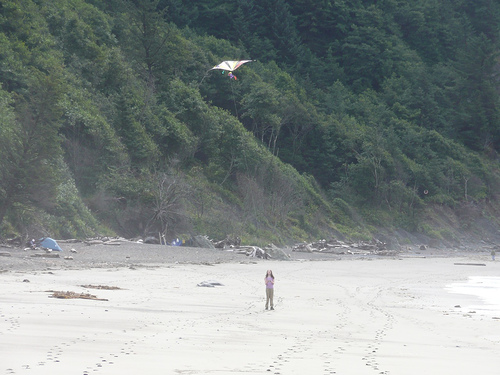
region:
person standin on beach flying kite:
[0, 266, 35, 313]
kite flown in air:
[210, 53, 258, 89]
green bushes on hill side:
[11, 7, 52, 46]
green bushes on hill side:
[45, 106, 89, 133]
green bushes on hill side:
[126, 143, 187, 176]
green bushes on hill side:
[254, 184, 307, 204]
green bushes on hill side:
[311, 85, 350, 138]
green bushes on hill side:
[391, 82, 429, 139]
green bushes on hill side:
[322, 51, 399, 98]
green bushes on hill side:
[433, 145, 465, 199]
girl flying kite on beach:
[239, 250, 291, 317]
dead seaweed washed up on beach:
[37, 266, 129, 318]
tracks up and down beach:
[23, 246, 420, 366]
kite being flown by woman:
[182, 48, 277, 89]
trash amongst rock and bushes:
[18, 200, 225, 275]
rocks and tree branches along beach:
[14, 228, 425, 269]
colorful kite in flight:
[189, 47, 268, 79]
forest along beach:
[6, 0, 499, 248]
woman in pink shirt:
[243, 261, 303, 321]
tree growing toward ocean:
[0, 58, 75, 240]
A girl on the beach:
[242, 258, 313, 326]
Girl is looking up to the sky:
[219, 233, 292, 328]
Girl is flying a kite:
[213, 24, 285, 325]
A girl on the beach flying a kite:
[153, 30, 292, 332]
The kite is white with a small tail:
[186, 48, 256, 98]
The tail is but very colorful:
[220, 68, 240, 89]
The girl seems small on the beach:
[244, 253, 286, 323]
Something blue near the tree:
[31, 222, 69, 266]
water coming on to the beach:
[441, 239, 491, 328]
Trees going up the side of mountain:
[291, 34, 431, 194]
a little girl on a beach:
[260, 265, 276, 311]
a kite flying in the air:
[197, 55, 257, 83]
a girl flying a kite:
[200, 52, 280, 312]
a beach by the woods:
[0, 240, 496, 371]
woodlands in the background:
[0, 0, 495, 246]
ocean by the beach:
[442, 267, 497, 333]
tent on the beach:
[30, 232, 63, 254]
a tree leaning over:
[0, 53, 68, 245]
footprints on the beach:
[263, 282, 399, 367]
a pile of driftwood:
[288, 229, 403, 259]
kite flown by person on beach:
[0, 59, 70, 100]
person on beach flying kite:
[254, 261, 282, 343]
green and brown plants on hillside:
[18, 172, 63, 218]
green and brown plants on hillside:
[26, 133, 87, 165]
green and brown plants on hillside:
[5, 60, 69, 100]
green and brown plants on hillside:
[81, 49, 140, 100]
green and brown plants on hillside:
[104, 128, 178, 197]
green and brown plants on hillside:
[203, 133, 271, 184]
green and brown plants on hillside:
[268, 168, 360, 229]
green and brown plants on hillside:
[332, 147, 437, 211]